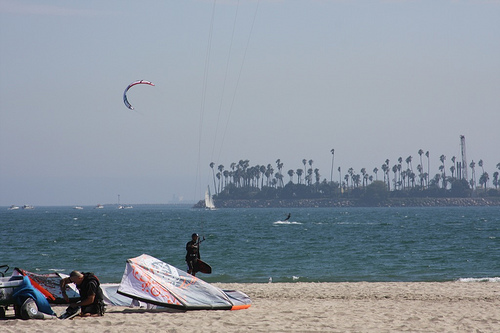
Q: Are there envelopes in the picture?
A: No, there are no envelopes.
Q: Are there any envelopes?
A: No, there are no envelopes.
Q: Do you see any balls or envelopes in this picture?
A: No, there are no envelopes or balls.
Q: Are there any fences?
A: No, there are no fences.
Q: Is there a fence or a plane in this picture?
A: No, there are no fences or airplanes.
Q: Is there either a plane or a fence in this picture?
A: No, there are no fences or airplanes.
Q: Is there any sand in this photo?
A: Yes, there is sand.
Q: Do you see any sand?
A: Yes, there is sand.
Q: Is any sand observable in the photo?
A: Yes, there is sand.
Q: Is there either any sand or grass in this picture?
A: Yes, there is sand.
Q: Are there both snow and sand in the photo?
A: No, there is sand but no snow.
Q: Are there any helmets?
A: No, there are no helmets.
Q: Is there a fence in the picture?
A: No, there are no fences.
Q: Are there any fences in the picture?
A: No, there are no fences.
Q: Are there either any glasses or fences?
A: No, there are no fences or glasses.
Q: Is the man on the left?
A: Yes, the man is on the left of the image.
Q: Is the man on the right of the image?
A: No, the man is on the left of the image.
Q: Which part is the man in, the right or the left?
A: The man is on the left of the image.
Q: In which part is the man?
A: The man is on the left of the image.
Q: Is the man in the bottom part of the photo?
A: Yes, the man is in the bottom of the image.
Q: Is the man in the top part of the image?
A: No, the man is in the bottom of the image.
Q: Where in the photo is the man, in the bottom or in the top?
A: The man is in the bottom of the image.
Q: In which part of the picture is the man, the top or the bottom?
A: The man is in the bottom of the image.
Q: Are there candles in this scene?
A: No, there are no candles.